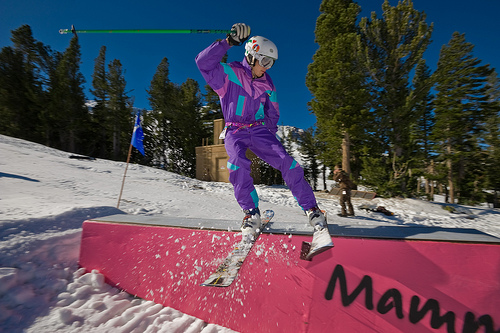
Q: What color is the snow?
A: White.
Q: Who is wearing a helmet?
A: The man in purple.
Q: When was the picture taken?
A: Daytime.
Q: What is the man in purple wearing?
A: A helmet.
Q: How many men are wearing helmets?
A: One.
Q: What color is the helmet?
A: White and red.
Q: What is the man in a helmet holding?
A: Ski poles.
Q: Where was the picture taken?
A: At a ski course.